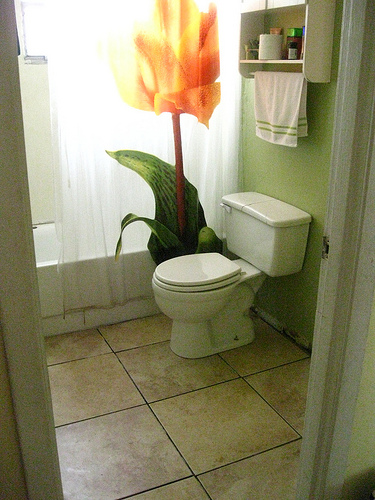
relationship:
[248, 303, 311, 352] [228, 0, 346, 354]
bottom of wall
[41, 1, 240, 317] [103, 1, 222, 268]
curtain with a tulip design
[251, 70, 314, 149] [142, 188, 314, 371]
towel above toilet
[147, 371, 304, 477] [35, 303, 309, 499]
tile on floor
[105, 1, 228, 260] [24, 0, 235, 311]
flower on curtain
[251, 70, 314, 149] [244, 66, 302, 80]
towel hanging on rod